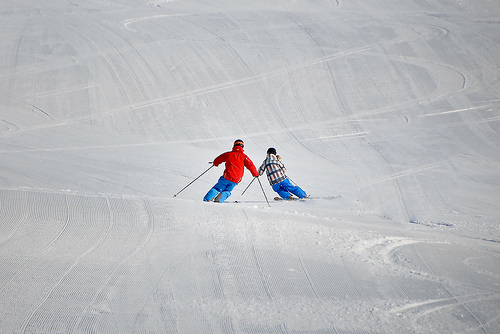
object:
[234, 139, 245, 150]
head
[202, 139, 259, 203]
man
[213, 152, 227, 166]
arm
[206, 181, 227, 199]
leg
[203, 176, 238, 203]
pants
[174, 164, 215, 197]
pole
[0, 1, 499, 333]
slope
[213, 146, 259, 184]
coat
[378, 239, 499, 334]
track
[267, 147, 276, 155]
hat